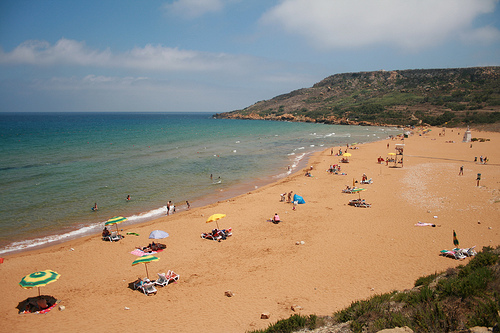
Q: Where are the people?
A: At the beach.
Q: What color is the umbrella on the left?
A: Green and yellow.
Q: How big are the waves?
A: Small.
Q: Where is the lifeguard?
A: There is not one.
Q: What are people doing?
A: Swimming.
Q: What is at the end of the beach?
A: A big hill.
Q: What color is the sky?
A: Blue.